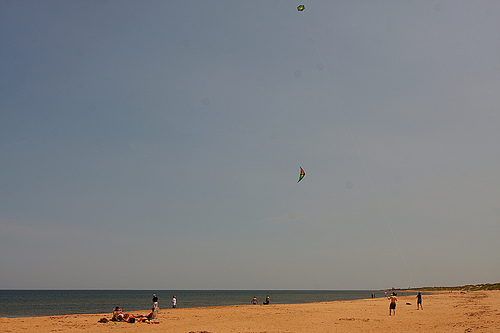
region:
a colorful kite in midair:
[292, 164, 317, 186]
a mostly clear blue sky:
[7, 13, 482, 288]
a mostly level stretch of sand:
[9, 288, 491, 330]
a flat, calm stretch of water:
[6, 289, 397, 313]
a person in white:
[166, 285, 183, 312]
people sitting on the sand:
[94, 295, 162, 332]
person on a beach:
[410, 286, 436, 309]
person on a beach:
[385, 283, 401, 315]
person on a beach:
[257, 280, 275, 312]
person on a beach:
[100, 300, 135, 320]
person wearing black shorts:
[366, 290, 411, 316]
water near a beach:
[8, 290, 59, 316]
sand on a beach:
[291, 304, 346, 330]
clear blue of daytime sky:
[0, 1, 498, 288]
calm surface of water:
[0, 289, 425, 317]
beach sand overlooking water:
[3, 288, 498, 330]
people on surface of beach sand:
[98, 289, 425, 324]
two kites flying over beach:
[1, 0, 498, 331]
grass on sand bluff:
[390, 282, 497, 294]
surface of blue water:
[0, 287, 424, 316]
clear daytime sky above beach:
[1, 1, 497, 331]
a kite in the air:
[283, 150, 313, 199]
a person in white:
[163, 289, 180, 313]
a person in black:
[141, 287, 160, 317]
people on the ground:
[98, 303, 143, 330]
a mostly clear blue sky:
[10, 7, 498, 299]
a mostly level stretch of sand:
[14, 309, 485, 330]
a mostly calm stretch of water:
[13, 282, 370, 316]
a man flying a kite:
[382, 288, 401, 327]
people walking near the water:
[238, 285, 280, 315]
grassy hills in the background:
[404, 277, 499, 297]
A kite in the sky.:
[278, 153, 322, 200]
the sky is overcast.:
[73, 74, 427, 159]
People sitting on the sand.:
[78, 293, 209, 325]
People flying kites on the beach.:
[326, 283, 478, 328]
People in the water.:
[236, 283, 275, 306]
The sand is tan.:
[238, 303, 364, 327]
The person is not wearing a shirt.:
[384, 294, 411, 306]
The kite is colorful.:
[268, 137, 325, 184]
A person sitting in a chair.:
[136, 305, 170, 322]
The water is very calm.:
[6, 288, 102, 318]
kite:
[296, 153, 307, 193]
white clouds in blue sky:
[43, 18, 80, 72]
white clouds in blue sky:
[397, 121, 438, 146]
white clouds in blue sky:
[375, 218, 407, 236]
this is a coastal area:
[4, 73, 456, 322]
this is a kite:
[260, 150, 363, 222]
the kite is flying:
[248, 133, 397, 258]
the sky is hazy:
[94, 175, 427, 315]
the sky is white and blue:
[141, 169, 293, 322]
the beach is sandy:
[257, 280, 342, 327]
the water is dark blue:
[133, 257, 220, 331]